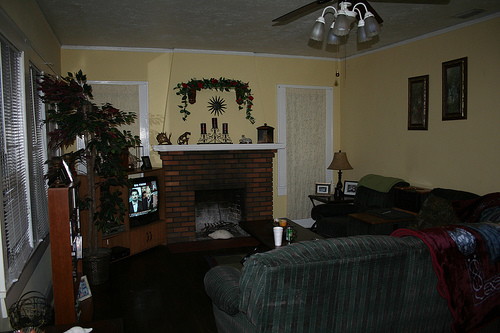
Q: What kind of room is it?
A: A living room.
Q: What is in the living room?
A: A couch.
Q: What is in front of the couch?
A: A fireplace.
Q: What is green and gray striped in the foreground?
A: Back of couch.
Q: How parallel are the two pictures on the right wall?
A: They are staggered.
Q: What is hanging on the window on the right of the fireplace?
A: Beige curtain.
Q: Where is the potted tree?
A: Left side of room.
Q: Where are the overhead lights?
A: Under the ceiling fan.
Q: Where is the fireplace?
A: Living room.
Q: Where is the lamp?
A: On table.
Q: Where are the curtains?
A: On windows.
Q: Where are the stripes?
A: On couch.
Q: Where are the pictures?
A: Hanging on wall.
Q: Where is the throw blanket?
A: On couch.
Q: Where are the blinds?
A: On left window.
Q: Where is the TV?
A: In stand.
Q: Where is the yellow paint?
A: The walls.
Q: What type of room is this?
A: Living room.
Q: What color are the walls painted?
A: Yellow.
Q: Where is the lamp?
A: In the corner.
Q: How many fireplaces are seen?
A: 1.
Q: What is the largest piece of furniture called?
A: A sofa.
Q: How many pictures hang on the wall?
A: 2.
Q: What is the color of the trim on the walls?
A: White.